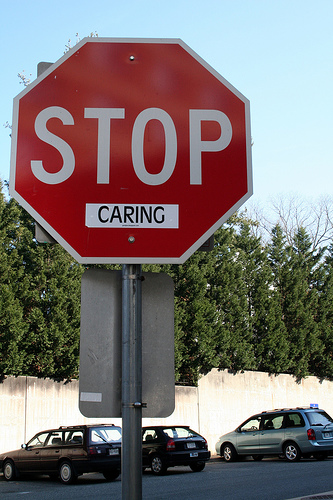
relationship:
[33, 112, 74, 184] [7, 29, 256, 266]
s on stop sign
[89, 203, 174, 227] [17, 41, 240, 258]
sticker on stop sign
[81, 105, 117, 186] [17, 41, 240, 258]
t on stop sign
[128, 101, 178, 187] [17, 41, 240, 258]
o on stop sign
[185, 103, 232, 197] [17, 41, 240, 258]
p on stop sign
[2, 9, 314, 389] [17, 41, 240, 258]
region around stop sign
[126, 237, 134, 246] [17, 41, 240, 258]
screw in stop sign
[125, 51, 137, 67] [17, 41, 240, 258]
screw in stop sign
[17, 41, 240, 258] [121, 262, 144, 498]
stop sign mounted on post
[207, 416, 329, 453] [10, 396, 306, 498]
van in parking lot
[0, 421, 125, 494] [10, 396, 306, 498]
station wagon in parking lot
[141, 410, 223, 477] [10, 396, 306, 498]
car in parking lot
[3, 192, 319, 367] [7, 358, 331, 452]
trees above wall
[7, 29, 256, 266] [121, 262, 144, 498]
stop sign attached to post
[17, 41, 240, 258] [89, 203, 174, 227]
stop sign with sticker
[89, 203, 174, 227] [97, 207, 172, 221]
sticker says caring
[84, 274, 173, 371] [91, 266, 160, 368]
back of sign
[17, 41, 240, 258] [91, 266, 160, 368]
stop sign above sign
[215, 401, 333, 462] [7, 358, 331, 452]
van in front of wall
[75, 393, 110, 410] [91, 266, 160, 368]
label on sign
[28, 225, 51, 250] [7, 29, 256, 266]
corner of stop sign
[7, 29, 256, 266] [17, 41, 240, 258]
stop sign behind stop sign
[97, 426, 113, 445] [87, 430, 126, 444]
windshield wiper on window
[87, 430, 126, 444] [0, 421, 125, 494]
window of station wagon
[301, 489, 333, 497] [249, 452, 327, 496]
manhole cover in roadway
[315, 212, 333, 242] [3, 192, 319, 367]
branches of trees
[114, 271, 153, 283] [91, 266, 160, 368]
clamp holding sign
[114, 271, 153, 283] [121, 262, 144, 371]
clamp holding post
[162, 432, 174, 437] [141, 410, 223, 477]
mirror on car